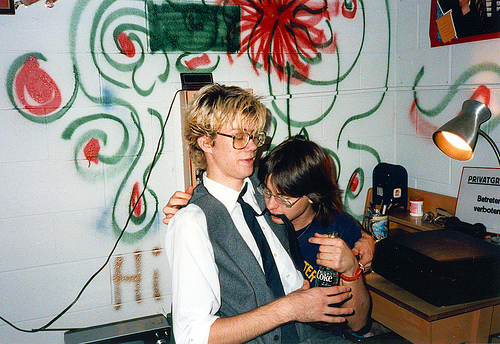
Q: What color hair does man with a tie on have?
A: Dirty Blonde.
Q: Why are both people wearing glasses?
A: So they can see properly.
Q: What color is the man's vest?
A: Gray.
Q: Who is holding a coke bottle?
A: The person in a blue t-shirt.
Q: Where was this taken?
A: In a dorm room.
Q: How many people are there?
A: Two.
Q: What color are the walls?
A: White.